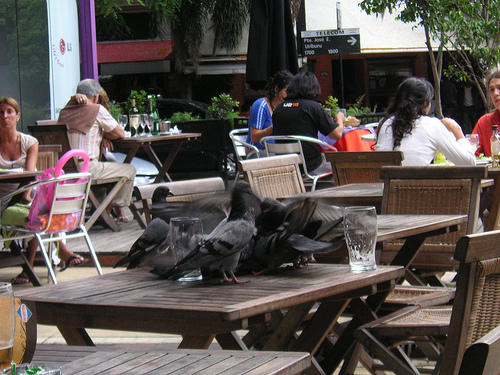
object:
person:
[463, 61, 498, 164]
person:
[270, 73, 343, 180]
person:
[0, 95, 88, 282]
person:
[243, 71, 293, 155]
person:
[372, 76, 477, 170]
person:
[54, 80, 136, 220]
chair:
[337, 227, 499, 375]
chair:
[235, 154, 305, 204]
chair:
[1, 171, 104, 285]